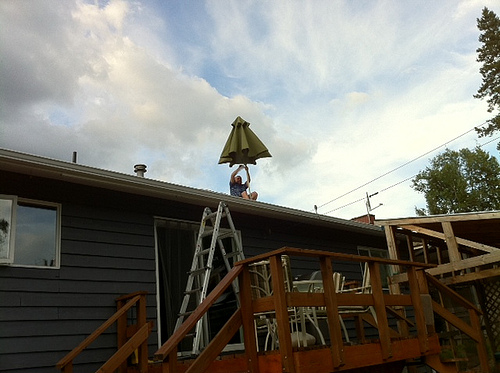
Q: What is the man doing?
A: Opening an Umbrella.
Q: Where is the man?
A: On the roof.